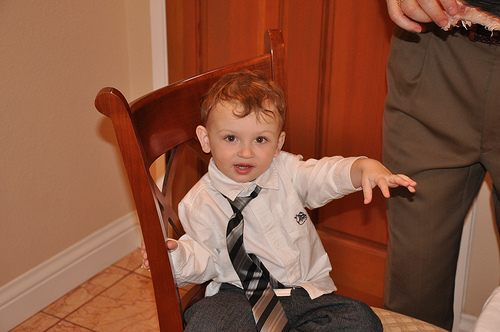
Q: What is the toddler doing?
A: Posing for the picture.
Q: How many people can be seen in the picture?
A: Two.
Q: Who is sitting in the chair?
A: A toddler boy.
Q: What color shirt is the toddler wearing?
A: White.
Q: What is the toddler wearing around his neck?
A: A tie.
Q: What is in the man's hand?
A: Food.